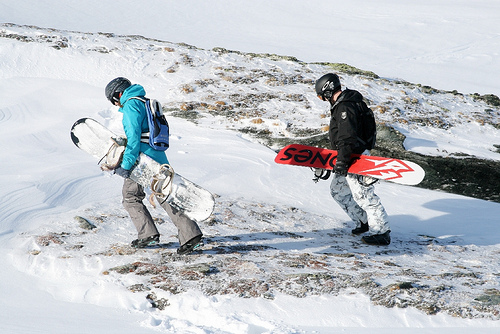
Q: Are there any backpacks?
A: Yes, there is a backpack.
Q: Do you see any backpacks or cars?
A: Yes, there is a backpack.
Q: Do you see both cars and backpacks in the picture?
A: No, there is a backpack but no cars.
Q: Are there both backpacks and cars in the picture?
A: No, there is a backpack but no cars.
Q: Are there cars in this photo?
A: No, there are no cars.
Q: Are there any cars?
A: No, there are no cars.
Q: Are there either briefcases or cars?
A: No, there are no cars or briefcases.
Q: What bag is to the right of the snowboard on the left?
A: The bag is a backpack.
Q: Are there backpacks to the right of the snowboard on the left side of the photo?
A: Yes, there is a backpack to the right of the snowboard.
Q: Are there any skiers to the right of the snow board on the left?
A: No, there is a backpack to the right of the snowboard.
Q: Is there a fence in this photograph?
A: No, there are no fences.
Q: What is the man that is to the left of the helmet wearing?
A: The man is wearing a backpack.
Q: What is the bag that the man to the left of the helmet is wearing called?
A: The bag is a backpack.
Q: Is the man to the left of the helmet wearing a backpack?
A: Yes, the man is wearing a backpack.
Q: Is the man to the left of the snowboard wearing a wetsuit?
A: No, the man is wearing a backpack.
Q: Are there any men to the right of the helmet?
A: No, the man is to the left of the helmet.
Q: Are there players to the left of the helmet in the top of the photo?
A: No, there is a man to the left of the helmet.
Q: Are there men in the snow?
A: Yes, there is a man in the snow.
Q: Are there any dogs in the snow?
A: No, there is a man in the snow.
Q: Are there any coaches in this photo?
A: No, there are no coaches.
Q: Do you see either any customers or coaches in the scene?
A: No, there are no coaches or customers.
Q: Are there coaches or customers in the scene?
A: No, there are no coaches or customers.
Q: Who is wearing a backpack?
A: The man is wearing a backpack.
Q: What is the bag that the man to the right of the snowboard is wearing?
A: The bag is a backpack.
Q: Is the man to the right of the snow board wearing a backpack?
A: Yes, the man is wearing a backpack.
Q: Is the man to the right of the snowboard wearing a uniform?
A: No, the man is wearing a backpack.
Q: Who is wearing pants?
A: The man is wearing pants.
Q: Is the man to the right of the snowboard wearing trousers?
A: Yes, the man is wearing trousers.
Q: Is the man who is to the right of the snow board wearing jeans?
A: No, the man is wearing trousers.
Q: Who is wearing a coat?
A: The man is wearing a coat.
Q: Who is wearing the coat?
A: The man is wearing a coat.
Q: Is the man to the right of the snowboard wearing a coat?
A: Yes, the man is wearing a coat.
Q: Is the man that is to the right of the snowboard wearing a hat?
A: No, the man is wearing a coat.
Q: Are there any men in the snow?
A: Yes, there is a man in the snow.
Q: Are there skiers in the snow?
A: No, there is a man in the snow.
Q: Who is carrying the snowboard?
A: The man is carrying the snowboard.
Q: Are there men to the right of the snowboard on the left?
A: Yes, there is a man to the right of the snowboard.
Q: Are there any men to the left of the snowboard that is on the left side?
A: No, the man is to the right of the snow board.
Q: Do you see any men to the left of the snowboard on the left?
A: No, the man is to the right of the snow board.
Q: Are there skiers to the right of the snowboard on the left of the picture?
A: No, there is a man to the right of the snowboard.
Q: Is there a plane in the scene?
A: No, there are no airplanes.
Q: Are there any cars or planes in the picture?
A: No, there are no planes or cars.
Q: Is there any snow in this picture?
A: Yes, there is snow.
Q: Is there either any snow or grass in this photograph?
A: Yes, there is snow.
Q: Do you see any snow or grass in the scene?
A: Yes, there is snow.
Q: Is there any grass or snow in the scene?
A: Yes, there is snow.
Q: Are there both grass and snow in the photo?
A: No, there is snow but no grass.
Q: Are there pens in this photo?
A: No, there are no pens.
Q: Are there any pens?
A: No, there are no pens.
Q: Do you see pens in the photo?
A: No, there are no pens.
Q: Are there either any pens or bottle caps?
A: No, there are no pens or bottle caps.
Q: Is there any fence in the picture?
A: No, there are no fences.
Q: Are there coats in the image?
A: Yes, there is a coat.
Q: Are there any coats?
A: Yes, there is a coat.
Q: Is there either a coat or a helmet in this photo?
A: Yes, there is a coat.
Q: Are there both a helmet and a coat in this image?
A: Yes, there are both a coat and a helmet.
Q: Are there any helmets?
A: Yes, there is a helmet.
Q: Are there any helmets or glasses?
A: Yes, there is a helmet.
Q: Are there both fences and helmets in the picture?
A: No, there is a helmet but no fences.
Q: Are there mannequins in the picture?
A: No, there are no mannequins.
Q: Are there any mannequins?
A: No, there are no mannequins.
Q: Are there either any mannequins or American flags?
A: No, there are no mannequins or American flags.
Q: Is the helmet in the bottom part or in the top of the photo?
A: The helmet is in the top of the image.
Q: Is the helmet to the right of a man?
A: Yes, the helmet is to the right of a man.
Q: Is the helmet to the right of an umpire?
A: No, the helmet is to the right of a man.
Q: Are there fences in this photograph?
A: No, there are no fences.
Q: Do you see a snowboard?
A: Yes, there is a snowboard.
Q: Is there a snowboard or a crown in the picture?
A: Yes, there is a snowboard.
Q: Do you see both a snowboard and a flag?
A: No, there is a snowboard but no flags.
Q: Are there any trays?
A: No, there are no trays.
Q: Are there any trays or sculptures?
A: No, there are no trays or sculptures.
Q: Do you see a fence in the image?
A: No, there are no fences.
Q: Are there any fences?
A: No, there are no fences.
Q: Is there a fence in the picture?
A: No, there are no fences.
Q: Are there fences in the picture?
A: No, there are no fences.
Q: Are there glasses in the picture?
A: No, there are no glasses.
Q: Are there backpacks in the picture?
A: Yes, there is a backpack.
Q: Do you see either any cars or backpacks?
A: Yes, there is a backpack.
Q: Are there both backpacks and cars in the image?
A: No, there is a backpack but no cars.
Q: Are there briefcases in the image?
A: No, there are no briefcases.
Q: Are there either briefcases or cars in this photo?
A: No, there are no briefcases or cars.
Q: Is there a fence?
A: No, there are no fences.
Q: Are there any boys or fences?
A: No, there are no fences or boys.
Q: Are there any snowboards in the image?
A: Yes, there is a snowboard.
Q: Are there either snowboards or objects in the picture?
A: Yes, there is a snowboard.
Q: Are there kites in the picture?
A: No, there are no kites.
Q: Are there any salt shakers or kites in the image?
A: No, there are no kites or salt shakers.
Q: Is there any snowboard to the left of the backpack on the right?
A: Yes, there is a snowboard to the left of the backpack.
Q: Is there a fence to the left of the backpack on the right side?
A: No, there is a snowboard to the left of the backpack.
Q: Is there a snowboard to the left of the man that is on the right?
A: Yes, there is a snowboard to the left of the man.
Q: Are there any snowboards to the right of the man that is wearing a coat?
A: No, the snowboard is to the left of the man.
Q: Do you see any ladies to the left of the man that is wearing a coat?
A: No, there is a snowboard to the left of the man.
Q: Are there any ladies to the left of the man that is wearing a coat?
A: No, there is a snowboard to the left of the man.